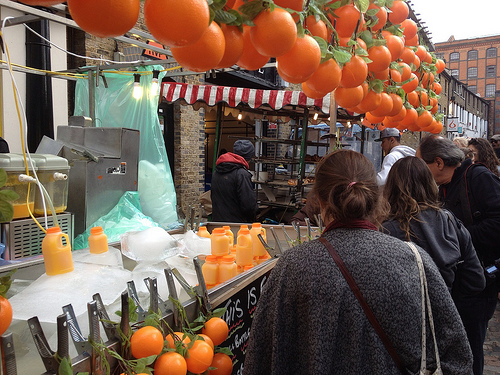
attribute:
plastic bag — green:
[62, 59, 192, 239]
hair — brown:
[384, 155, 446, 241]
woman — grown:
[384, 155, 488, 296]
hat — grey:
[228, 127, 263, 163]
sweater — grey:
[239, 227, 473, 372]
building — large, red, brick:
[435, 31, 499, 105]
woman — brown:
[382, 150, 489, 305]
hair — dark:
[387, 154, 442, 228]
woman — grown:
[271, 149, 474, 371]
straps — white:
[422, 264, 441, 367]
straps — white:
[405, 242, 427, 373]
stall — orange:
[1, 0, 445, 374]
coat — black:
[216, 159, 258, 221]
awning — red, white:
[160, 77, 340, 116]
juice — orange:
[7, 188, 35, 221]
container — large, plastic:
[1, 150, 33, 225]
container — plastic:
[26, 150, 71, 220]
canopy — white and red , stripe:
[153, 67, 340, 133]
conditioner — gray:
[45, 17, 208, 117]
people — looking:
[281, 148, 498, 373]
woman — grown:
[209, 165, 469, 363]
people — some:
[248, 149, 474, 373]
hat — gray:
[230, 137, 256, 154]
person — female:
[244, 147, 479, 369]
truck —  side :
[8, 131, 299, 372]